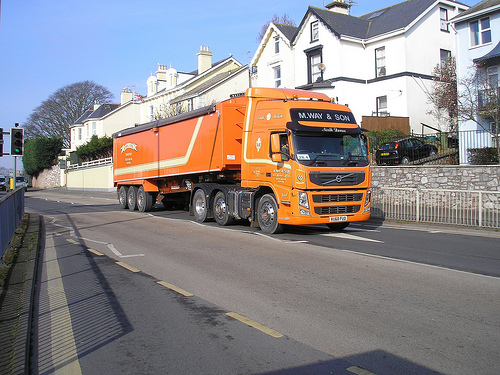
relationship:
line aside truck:
[114, 111, 202, 177] [107, 86, 377, 233]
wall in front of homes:
[363, 162, 498, 227] [48, 20, 498, 177]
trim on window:
[298, 42, 328, 89] [302, 46, 336, 92]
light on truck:
[298, 191, 309, 210] [107, 86, 377, 233]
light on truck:
[362, 188, 372, 205] [107, 86, 377, 233]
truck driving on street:
[107, 86, 377, 233] [37, 191, 498, 371]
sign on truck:
[102, 111, 159, 161] [67, 66, 424, 231]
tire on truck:
[257, 193, 281, 235] [104, 73, 389, 263]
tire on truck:
[213, 192, 234, 226] [107, 86, 377, 233]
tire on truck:
[257, 193, 281, 235] [107, 86, 377, 233]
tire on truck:
[190, 189, 205, 221] [107, 86, 377, 233]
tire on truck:
[136, 186, 152, 212] [107, 86, 377, 233]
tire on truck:
[115, 183, 124, 209] [107, 86, 377, 233]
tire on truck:
[123, 182, 137, 212] [107, 86, 377, 233]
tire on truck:
[213, 184, 233, 221] [107, 86, 377, 233]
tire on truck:
[248, 185, 279, 233] [107, 86, 377, 233]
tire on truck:
[135, 178, 152, 215] [107, 86, 377, 233]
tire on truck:
[122, 175, 139, 211] [107, 86, 377, 233]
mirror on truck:
[265, 122, 290, 164] [99, 71, 355, 241]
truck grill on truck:
[386, 180, 498, 246] [106, 81, 377, 251]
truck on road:
[111, 86, 372, 234] [77, 212, 476, 359]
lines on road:
[131, 246, 259, 363] [0, 188, 500, 375]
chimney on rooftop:
[196, 44, 213, 74] [141, 55, 231, 101]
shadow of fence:
[380, 193, 466, 223] [422, 172, 486, 216]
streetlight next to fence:
[7, 122, 25, 178] [33, 162, 108, 192]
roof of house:
[270, 3, 440, 42] [249, 13, 482, 175]